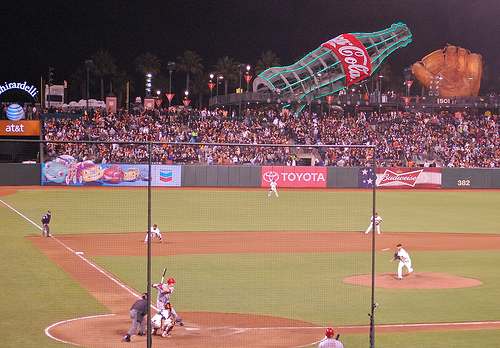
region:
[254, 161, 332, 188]
red and white car manufacturer on banner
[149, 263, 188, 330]
baseball batter preparing to hit ball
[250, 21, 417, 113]
green coca cola bottle image in baseball field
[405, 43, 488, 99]
catcher's mitt image in baseball field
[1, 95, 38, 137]
phone carrier banner in baseball field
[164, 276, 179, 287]
red helmet on baseball pitcher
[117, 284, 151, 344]
baseball umpire in grey uniform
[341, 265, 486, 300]
round dirt pitchers mound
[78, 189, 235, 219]
patch of green grass in baseball field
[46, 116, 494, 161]
baseball game patrons in bleachers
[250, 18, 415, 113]
The larger than life coke bottle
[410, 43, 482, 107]
The larger than life baseball gloves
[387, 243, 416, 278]
The pitcher on the mound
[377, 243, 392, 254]
The ball in the air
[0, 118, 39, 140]
The orange ATT add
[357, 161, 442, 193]
The beer add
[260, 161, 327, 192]
The red car maker add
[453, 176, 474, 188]
The number 382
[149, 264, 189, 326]
The player up to bat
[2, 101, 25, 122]
The blue world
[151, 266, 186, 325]
baseball player at bat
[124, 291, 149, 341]
umpire on baseball field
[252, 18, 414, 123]
giant neon Coca-Cola sign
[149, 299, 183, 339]
crouched baseball catcher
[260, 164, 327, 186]
red and white Toyota ad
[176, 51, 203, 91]
tall palm tree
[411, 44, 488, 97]
giant brown catcher's mitt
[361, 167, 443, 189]
red white and blue Budweiser ad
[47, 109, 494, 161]
crowd at baseball stadium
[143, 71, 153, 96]
tall stacked light fixture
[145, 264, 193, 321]
The batter is wearing red and black.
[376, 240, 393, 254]
The ball is in mid air.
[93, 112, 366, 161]
The stands are full of people.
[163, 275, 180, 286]
The batters helmet is red.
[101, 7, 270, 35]
It is night in the photo.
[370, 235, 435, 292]
The pitcher has thrown the ball.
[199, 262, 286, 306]
The grass is green.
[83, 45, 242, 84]
Trees are in the background.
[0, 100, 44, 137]
A sign for At&t.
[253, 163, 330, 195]
A sign for Toyota.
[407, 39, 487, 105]
the baseball mitt is brown.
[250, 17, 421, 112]
cola bottle is lit up.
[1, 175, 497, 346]
people playing baseball on a field.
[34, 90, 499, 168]
people sitting on the stands.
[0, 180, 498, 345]
the grass is green.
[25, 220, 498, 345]
the dirt is brown.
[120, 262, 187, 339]
people at home plate.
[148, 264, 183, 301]
player holding baseball bat.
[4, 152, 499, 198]
the fence is green.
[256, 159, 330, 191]
red sign on fence.